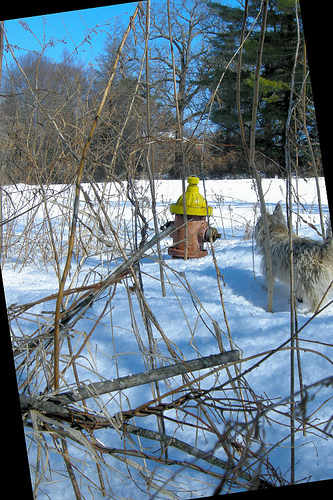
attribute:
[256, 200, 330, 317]
dog — small, standing, white, scruffy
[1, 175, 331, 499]
snow — bluish, white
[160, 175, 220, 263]
fire hydrant — red, yellow, orange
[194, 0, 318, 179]
pine tree — green, tall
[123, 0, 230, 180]
tree — bare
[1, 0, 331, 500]
branches — dead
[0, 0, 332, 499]
day — sunny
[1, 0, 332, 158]
sky — blue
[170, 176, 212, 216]
yellow — faded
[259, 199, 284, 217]
ears — small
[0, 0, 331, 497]
twigs — bare